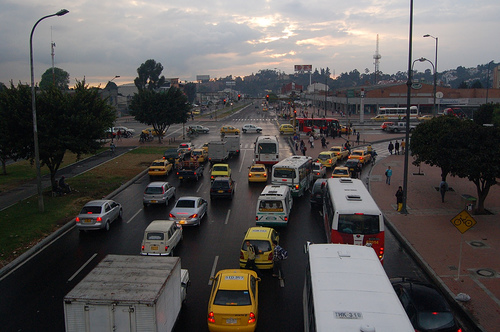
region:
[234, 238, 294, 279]
the men walking in the road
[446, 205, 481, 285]
the sign on the sidewalk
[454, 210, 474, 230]
the bike on the yellow sign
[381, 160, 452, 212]
the poeple on the sidewalk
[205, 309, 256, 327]
the tail lights on the cab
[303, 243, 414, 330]
the roof of the bus on the road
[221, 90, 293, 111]
the red lights on the street lights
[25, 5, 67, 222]
the light pole in the grass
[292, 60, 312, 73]
the red sign in the distnace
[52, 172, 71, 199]
the people sitting on the bench in the grass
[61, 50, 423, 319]
traffic on a city street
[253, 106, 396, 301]
a traffic jam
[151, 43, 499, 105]
buildings and hills in the distance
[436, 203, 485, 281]
a yellow bicycle sign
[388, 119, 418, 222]
people standing on a street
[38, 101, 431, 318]
cars on a street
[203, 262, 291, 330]
a yellow taxi cab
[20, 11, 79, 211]
a street light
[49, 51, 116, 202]
a person sitting down under a tree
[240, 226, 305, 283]
people standing outside a car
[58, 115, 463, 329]
many vehicles at an intersection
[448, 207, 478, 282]
yellow and black bicycle path sign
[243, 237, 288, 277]
two men walking across a road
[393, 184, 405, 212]
person standing on the sidewalk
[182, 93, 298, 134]
street lights are red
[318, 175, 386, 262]
red and white passenger bus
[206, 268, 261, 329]
yellow taxi cab with brake lights on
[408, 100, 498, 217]
group of trees on the sidewalk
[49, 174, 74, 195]
two people sitting on grass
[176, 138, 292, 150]
crosswalk across the road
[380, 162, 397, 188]
person in blue shirt walking down sidewalk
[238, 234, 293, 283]
two men walking across street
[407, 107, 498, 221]
tree growing in sidewalk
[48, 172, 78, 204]
people sitting underneath of tree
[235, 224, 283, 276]
yellow car stopped in street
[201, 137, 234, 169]
white truck stopped at traffic light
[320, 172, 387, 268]
bus stopped on street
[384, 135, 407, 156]
group of people standing on sidewalk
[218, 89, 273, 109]
group of traffic lights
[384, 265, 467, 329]
black car on street beside of bus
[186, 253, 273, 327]
a yellow taxi cab on the road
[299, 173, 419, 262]
a white and red bus on the road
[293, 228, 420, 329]
a white bus on the road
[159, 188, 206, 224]
a silver car on the road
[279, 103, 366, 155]
a red bus on the road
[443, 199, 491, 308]
a yellow and black bike sign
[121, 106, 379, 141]
cars driving on the road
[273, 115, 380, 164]
people crossing the street